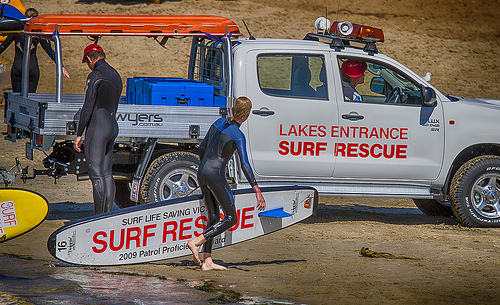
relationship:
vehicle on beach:
[3, 0, 499, 228] [417, 18, 479, 53]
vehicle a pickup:
[44, 13, 484, 172] [19, 39, 484, 190]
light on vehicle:
[318, 13, 387, 41] [3, 0, 499, 228]